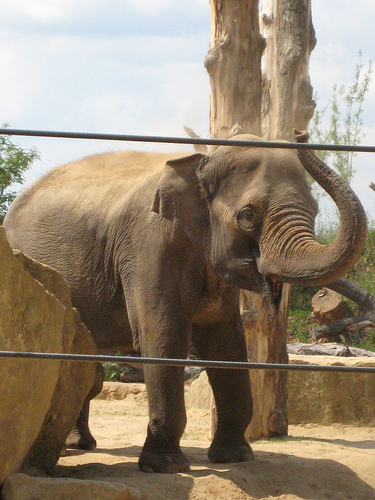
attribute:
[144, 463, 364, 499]
surface — brown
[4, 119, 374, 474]
elephant — gray, grey, happy, brown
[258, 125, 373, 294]
trunk — curled, brown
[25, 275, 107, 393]
rock — tan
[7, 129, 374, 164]
fence — metal, wire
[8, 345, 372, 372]
wire — grey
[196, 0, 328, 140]
tree — gray, bark less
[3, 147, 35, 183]
tree leaves — in the corner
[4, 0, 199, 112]
sky — cloudy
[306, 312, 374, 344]
log — two colors, flat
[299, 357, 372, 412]
boulder — tan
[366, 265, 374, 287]
grass — patchy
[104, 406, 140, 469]
dirt — brown